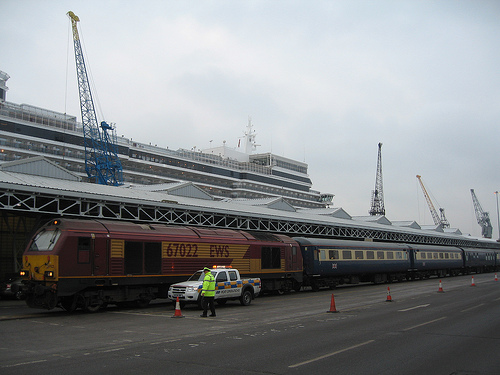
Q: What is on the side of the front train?
A: Truck.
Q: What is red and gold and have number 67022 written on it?
A: Train.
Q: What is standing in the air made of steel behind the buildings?
A: Cranes.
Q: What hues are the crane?
A: Blue and yellow.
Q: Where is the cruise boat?
A: In port.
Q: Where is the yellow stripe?
A: On the train cars.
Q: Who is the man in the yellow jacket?
A: A worker for the dock.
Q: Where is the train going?
A: To its next destination.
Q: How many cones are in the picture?
A: 6.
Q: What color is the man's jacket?
A: Bright yellow.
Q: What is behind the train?
A: A boat.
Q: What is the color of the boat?
A: White.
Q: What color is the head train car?
A: Red.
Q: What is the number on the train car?
A: 67022.